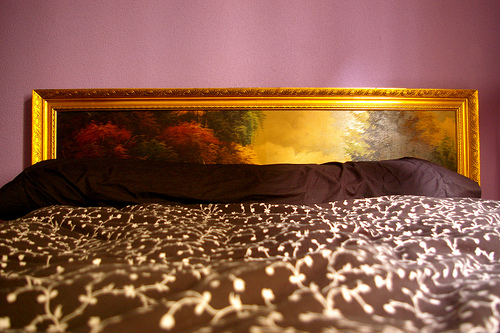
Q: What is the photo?
A: A painting.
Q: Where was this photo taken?
A: In a bedroom.